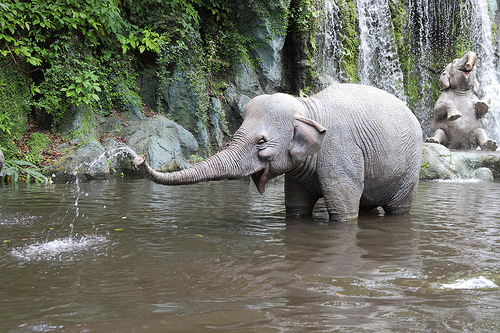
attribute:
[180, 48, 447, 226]
elephant — grey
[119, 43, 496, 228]
elephants — grey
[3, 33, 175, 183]
large rocks —  large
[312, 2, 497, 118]
water — running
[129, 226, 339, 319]
water — brown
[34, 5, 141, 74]
leaves — green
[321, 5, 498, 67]
waterfall — green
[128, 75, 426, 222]
elephant — baby, grey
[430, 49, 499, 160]
elephant — baby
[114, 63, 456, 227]
elephant — happy looking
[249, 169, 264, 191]
mouth — open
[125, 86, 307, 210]
elephant water —  baby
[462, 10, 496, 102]
water — white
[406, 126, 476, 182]
boulder — gray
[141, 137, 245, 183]
trunk —  elephant's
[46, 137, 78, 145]
leaves —  brown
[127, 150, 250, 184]
trunk —  elephant's